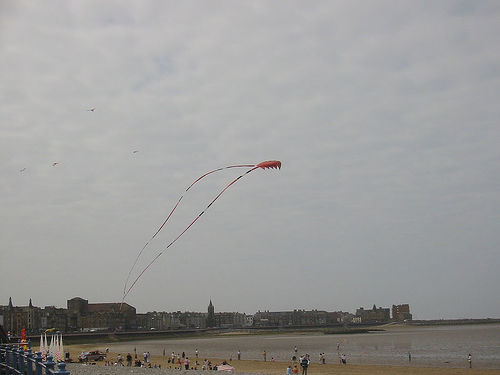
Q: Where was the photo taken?
A: At the beach.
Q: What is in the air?
A: Kites.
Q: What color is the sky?
A: Grey.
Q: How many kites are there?
A: One.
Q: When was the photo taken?
A: Daytime.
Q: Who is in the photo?
A: Beachgoers.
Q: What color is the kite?
A: Red.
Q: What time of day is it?
A: Afternoon.